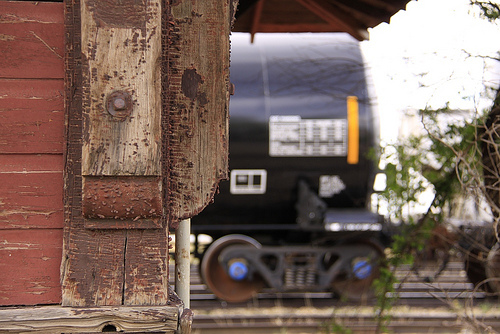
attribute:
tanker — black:
[187, 5, 411, 283]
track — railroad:
[165, 246, 469, 326]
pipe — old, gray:
[168, 197, 203, 324]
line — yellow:
[322, 85, 378, 179]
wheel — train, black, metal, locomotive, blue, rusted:
[187, 214, 295, 310]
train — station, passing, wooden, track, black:
[146, 18, 440, 297]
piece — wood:
[41, 230, 171, 328]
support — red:
[231, 8, 368, 60]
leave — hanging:
[339, 95, 488, 325]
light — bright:
[363, 173, 426, 211]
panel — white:
[270, 112, 369, 179]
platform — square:
[162, 234, 388, 322]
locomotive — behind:
[161, 32, 420, 314]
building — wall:
[3, 8, 419, 263]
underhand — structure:
[220, 4, 406, 46]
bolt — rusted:
[103, 87, 155, 122]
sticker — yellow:
[306, 85, 378, 187]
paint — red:
[12, 87, 81, 200]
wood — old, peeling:
[65, 10, 158, 93]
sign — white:
[224, 158, 283, 201]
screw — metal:
[102, 90, 137, 125]